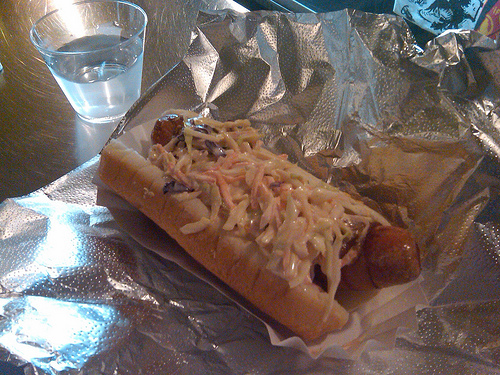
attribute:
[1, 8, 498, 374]
foil — silver, metallic, crumpled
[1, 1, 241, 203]
table — shiny, metal, textured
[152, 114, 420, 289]
hot dog — brown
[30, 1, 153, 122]
cup — plastic, small, indoors, clear, half full, half empty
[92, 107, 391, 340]
bun — brown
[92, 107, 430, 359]
paper holder — white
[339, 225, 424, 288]
hot dog end — cooked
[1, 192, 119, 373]
reflection — bright, blue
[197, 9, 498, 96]
edge — crumpled